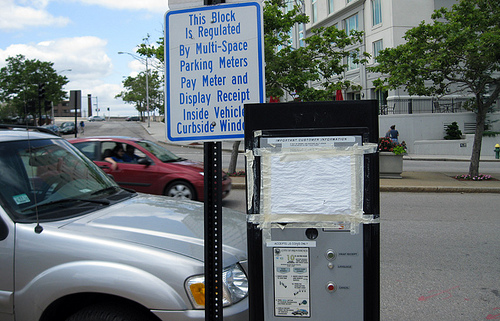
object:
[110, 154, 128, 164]
shirt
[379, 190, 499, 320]
pavement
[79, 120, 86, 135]
person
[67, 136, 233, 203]
car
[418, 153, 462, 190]
ground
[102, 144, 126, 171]
person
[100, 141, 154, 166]
window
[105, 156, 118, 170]
arm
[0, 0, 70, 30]
clouds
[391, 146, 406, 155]
plant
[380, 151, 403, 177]
pot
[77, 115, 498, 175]
road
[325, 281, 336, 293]
button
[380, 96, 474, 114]
chain fence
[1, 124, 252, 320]
car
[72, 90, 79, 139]
pole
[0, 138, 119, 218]
windshield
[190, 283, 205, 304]
headlight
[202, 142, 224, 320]
black pole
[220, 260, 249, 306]
headlight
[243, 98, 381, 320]
parking meter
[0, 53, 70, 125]
tree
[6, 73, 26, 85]
leaves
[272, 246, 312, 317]
instructions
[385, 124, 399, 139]
person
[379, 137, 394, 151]
plant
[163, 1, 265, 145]
sign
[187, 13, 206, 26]
writing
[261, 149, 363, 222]
paper